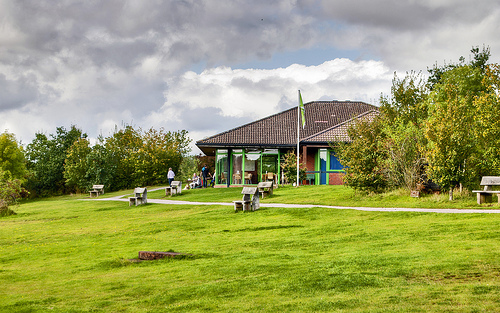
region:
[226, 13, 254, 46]
part of a cloud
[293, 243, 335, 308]
part of a field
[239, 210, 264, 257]
part of a ground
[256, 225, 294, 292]
part of a field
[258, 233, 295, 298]
part o fa ground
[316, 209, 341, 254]
part of a grass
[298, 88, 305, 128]
A flag drooping down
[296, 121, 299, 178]
A whtie flag pole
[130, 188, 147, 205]
a seat in the grass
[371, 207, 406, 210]
A walk way between the grass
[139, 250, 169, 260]
A tree trunk sticking out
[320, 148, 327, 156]
Glass reflecting the light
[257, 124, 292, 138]
Brownish tiles on the roof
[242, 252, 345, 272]
Green grass brightened by light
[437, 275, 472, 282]
A dark patch on the grass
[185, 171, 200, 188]
A person sitting down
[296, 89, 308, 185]
flag hanging on a pole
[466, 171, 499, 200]
bench in the grass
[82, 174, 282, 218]
group of benches in the grass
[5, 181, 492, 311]
bright green grass on the ground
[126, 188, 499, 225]
path cutting through the grass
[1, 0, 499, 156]
thick clouds in the sky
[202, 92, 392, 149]
brown roof on the building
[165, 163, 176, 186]
person walking on the path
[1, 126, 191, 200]
row of trees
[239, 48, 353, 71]
patch of blue sky visible between the clouds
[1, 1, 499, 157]
A mostly cloudy sky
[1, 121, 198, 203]
A grouping of trees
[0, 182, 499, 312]
A vibrant green healthy lawn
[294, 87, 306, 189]
A raised green flag on a flagpole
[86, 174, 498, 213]
A group of benches in the grass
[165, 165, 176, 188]
A man standing in the grass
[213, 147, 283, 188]
A row of green framed windows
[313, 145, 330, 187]
A blue entrance door with a green border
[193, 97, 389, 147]
A brown tiled roof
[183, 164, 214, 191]
Some people outside in the yard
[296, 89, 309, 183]
green flag on pole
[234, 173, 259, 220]
bench along the sidewalk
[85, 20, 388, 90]
clouds in the sky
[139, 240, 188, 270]
slab of cement on the yard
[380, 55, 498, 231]
bench sitting under trees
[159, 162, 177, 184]
man walking in the yard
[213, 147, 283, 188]
green patio porch on the house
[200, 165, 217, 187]
man cooking on grill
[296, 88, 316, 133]
green flag on a pole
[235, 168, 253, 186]
patio furniture inside